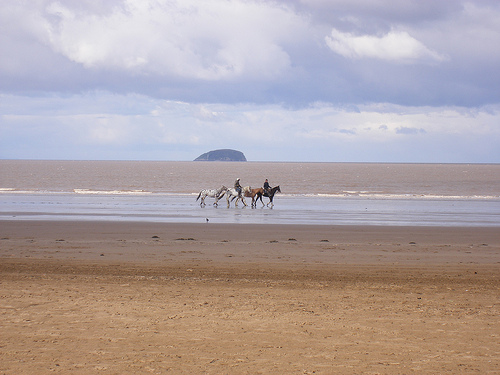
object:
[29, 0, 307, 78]
clouds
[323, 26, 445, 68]
clouds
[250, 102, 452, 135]
clouds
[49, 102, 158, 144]
clouds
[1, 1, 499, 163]
sky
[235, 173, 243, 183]
hat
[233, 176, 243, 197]
person